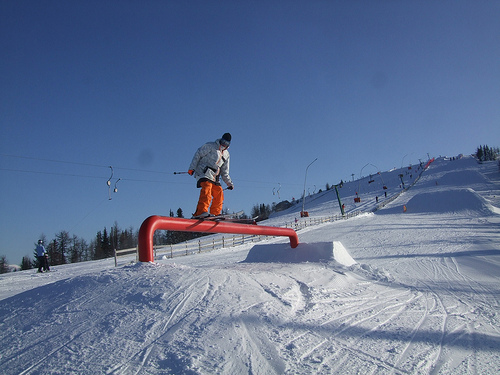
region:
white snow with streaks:
[12, 271, 109, 371]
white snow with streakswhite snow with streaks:
[42, 286, 193, 354]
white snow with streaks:
[143, 288, 216, 340]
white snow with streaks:
[215, 260, 266, 310]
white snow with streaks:
[281, 290, 331, 351]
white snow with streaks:
[353, 265, 395, 340]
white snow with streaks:
[410, 214, 450, 301]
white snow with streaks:
[351, 231, 373, 241]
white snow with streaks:
[226, 276, 450, 348]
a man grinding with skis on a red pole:
[186, 118, 257, 233]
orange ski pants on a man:
[190, 168, 225, 226]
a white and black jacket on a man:
[187, 130, 237, 190]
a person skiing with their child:
[26, 231, 63, 282]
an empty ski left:
[100, 150, 120, 211]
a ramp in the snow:
[246, 225, 361, 285]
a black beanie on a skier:
[217, 130, 233, 150]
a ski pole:
[162, 160, 203, 176]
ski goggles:
[216, 130, 229, 148]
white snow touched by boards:
[18, 305, 56, 373]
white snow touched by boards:
[60, 295, 123, 355]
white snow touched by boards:
[107, 274, 202, 370]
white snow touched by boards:
[247, 267, 315, 367]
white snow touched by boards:
[326, 257, 373, 372]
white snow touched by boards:
[391, 196, 472, 288]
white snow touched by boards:
[25, 209, 233, 372]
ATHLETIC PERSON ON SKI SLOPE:
[178, 125, 241, 222]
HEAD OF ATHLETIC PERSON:
[211, 128, 233, 148]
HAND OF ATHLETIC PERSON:
[224, 178, 237, 192]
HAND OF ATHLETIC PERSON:
[184, 165, 195, 177]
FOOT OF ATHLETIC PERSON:
[189, 208, 210, 218]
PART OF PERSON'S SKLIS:
[193, 214, 236, 222]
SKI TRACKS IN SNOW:
[228, 300, 383, 374]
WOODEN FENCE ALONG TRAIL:
[181, 233, 236, 245]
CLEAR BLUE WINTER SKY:
[78, 47, 196, 100]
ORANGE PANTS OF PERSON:
[197, 183, 227, 217]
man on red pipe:
[183, 106, 239, 228]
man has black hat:
[211, 131, 253, 166]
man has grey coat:
[200, 114, 224, 178]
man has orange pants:
[203, 180, 225, 225]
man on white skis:
[175, 207, 232, 227]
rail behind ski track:
[125, 152, 433, 270]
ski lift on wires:
[89, 137, 144, 245]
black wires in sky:
[10, 153, 152, 201]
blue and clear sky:
[111, 32, 223, 129]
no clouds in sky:
[96, 34, 221, 141]